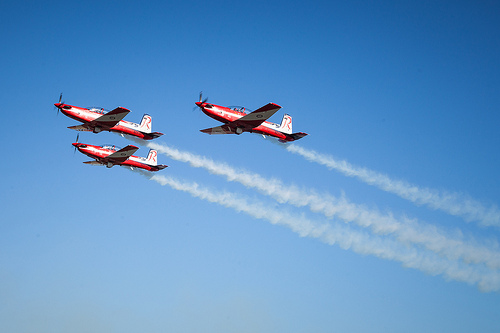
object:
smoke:
[137, 142, 500, 302]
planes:
[54, 88, 308, 172]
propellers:
[46, 93, 71, 116]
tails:
[277, 119, 309, 145]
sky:
[0, 3, 499, 332]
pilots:
[82, 92, 251, 175]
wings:
[244, 102, 281, 131]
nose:
[39, 93, 220, 164]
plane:
[192, 91, 306, 145]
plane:
[52, 92, 164, 147]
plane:
[72, 134, 170, 177]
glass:
[86, 90, 251, 176]